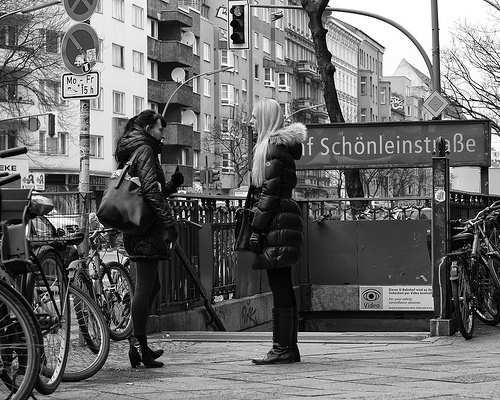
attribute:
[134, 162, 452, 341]
subway — underground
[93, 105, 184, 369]
woman — standing, talking, brunette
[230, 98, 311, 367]
woman — standing, blonde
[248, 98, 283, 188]
hair — blonde, long, straight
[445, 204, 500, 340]
bicycle — leaning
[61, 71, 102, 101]
sign — black, white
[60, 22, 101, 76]
sign — round, circular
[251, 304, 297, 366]
boot — leather, black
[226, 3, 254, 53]
signal — hanging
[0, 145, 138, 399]
bikes — parked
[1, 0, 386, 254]
buildings — huge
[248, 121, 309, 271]
jacket — puffy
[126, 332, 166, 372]
boot — mid calf, leather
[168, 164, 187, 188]
glove — dark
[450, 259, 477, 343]
wheel — rubber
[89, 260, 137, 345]
wheel — rubber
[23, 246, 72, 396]
wheel — rubber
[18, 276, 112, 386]
wheel — rubber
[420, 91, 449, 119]
sign — diamond-shaped